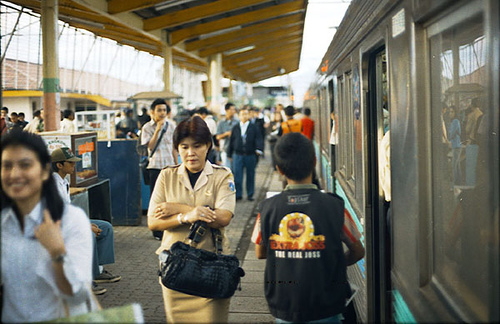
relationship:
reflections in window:
[438, 85, 487, 185] [431, 28, 487, 298]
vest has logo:
[262, 203, 354, 315] [268, 211, 351, 267]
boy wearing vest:
[246, 135, 355, 316] [262, 203, 354, 315]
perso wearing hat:
[46, 141, 125, 292] [54, 145, 82, 170]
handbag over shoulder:
[151, 124, 170, 164] [134, 117, 186, 125]